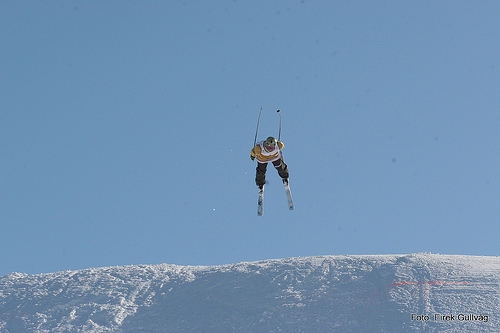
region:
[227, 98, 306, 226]
a skier in midair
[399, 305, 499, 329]
black logo of the photographer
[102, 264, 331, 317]
white snow on the mountain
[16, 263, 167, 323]
tracks in the snow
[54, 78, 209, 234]
clear blue skies over the mountain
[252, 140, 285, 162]
the skier's white and yellow jacket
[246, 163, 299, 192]
the skier's black snow pants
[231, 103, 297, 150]
the skier's poles raised into the air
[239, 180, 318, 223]
the skier's white skis in the air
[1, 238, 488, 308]
the white snow covered peak of the hill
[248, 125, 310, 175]
Person holding 2 ski poles.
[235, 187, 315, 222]
Skis on person's feet.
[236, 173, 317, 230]
Skis are white in color.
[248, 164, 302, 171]
Person wearing black pants.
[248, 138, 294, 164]
Person wearing tan shirt.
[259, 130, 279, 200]
Person wearing white vest.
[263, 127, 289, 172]
Helmet on person's head.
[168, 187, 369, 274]
Person is soaring through air.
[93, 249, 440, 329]
Ground is covered in snow.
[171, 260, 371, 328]
Snow on ground is white in color.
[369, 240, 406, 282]
edge of a hill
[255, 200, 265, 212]
part of a board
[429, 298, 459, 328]
part of a grpahic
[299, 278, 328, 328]
part of a shade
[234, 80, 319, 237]
skier flying through the air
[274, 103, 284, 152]
skier holding a ski pole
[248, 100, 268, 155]
skier holding a ski pole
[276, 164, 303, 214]
ski on the skier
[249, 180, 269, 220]
ski on the skier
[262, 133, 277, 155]
helmet on the skier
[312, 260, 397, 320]
snow on the mountain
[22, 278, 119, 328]
snow on the mountain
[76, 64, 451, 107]
blue sky behind the skier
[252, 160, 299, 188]
pants on the skier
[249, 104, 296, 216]
A skier flying in the air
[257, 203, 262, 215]
The right ski in the air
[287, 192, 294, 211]
Left ski with sky in the background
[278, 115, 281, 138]
A ski pole in the air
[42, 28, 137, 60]
A blue clear sky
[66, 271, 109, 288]
Snow shining in the sun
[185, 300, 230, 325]
A shadow cast in the snow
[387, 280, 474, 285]
A red strip on the snow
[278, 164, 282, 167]
A white band on the trousers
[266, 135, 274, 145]
Protective gear on the head